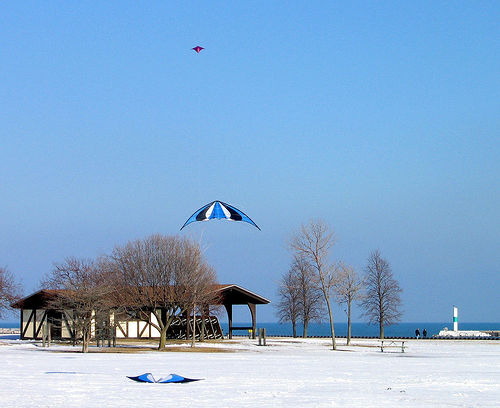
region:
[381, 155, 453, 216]
part of the sky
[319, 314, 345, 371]
stem of a tree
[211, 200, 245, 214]
edge of a kite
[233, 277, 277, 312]
edge of a roof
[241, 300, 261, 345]
part of a stand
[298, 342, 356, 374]
part of some sand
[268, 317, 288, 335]
part of some water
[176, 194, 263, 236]
a blue, white, and black kite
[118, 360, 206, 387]
a kite on the ground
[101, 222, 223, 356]
a dormant tree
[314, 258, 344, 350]
a tree trunk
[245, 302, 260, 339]
a wooden beam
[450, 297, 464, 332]
a white pole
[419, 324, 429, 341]
a person on the snow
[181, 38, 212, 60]
a pink kite in the sky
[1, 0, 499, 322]
a clear blue sky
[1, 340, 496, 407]
a white snowy park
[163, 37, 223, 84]
kite flying in sky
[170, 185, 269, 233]
kite flying in sky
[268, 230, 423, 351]
group of trees standing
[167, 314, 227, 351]
group of picnic tables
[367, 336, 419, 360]
a single picnic table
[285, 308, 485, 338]
blue ocean in background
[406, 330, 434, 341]
two people walking on the ocean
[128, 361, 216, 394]
kite laying on ground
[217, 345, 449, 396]
snow covering park ground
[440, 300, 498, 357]
pole standing on edge of ocean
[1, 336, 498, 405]
a sandy beach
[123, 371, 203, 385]
a kite on the ground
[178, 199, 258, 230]
a kite in the air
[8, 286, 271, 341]
a small brown and white building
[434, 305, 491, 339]
a boat in the background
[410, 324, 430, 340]
two people standing by the water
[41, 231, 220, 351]
a cluster of trees in front of the building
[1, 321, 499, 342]
a body of water in the background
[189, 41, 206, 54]
a pink kite high in the air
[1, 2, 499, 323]
a cloudless blue sky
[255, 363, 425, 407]
a white sandy beach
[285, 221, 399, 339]
a group of leafless trees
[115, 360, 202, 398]
a blue and white kite on the ground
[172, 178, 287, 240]
a blue and white kite taking off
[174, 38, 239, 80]
a red and blue kite flying high in the sky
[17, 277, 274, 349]
a brown and white beach povilion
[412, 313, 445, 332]
blue ocean waters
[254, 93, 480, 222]
crystal clear blue sky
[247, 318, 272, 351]
two wooden posts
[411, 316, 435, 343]
two people wearing black jackets on a beach